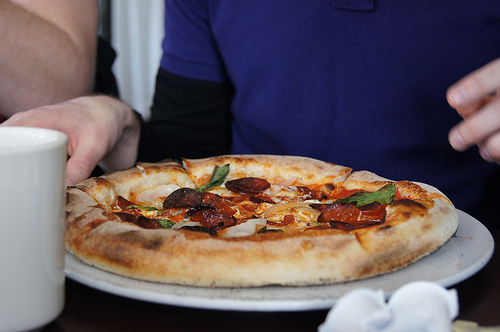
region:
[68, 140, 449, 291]
a pizza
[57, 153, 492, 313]
a pizza on a white plate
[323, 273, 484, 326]
a white crumpled napkin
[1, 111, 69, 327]
a white mug on a table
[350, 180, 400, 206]
a basil leaf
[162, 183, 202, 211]
a burned pepperoni slice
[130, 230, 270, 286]
a pizza crust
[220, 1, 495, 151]
a blue shirt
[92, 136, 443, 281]
a pizza with pepperoni and basil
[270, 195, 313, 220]
cheese on a pizza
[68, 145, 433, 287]
A round pizza on the plate.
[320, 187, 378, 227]
The pizza has pepperoni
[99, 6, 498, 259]
A person with a pizza in front of them.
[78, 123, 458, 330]
The pizza is on a white plate.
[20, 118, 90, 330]
A white cup is next to the plate.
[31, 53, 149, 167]
A person hand on the table.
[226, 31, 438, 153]
The person is wearing a blue shirt.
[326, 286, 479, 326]
A white napkin on the table.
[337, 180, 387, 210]
The pizza has spinach on top.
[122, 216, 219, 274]
The crust of the pizza is well done.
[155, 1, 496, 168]
Person wearing a blue shirt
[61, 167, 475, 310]
Pizza on a plate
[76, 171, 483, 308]
The plate is round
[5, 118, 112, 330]
The mug is white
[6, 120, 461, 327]
The mug is next to the plate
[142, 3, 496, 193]
Person wearing a long sleeve black shirt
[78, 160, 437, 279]
The pizza has a brown crust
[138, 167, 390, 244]
Red pepperoni on the pizza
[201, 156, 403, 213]
Green leaves on the pizza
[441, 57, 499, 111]
the finger of a person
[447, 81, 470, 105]
the finger nail of a person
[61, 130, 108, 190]
the thumb of a person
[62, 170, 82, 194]
the thumb nail of a person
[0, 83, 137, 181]
the hand of a person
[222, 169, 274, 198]
a piece of pepperoni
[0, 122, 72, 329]
a white coffee mug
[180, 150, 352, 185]
the crust of a pizza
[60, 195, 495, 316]
a white porcelain plate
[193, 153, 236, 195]
a green leaf on the pizza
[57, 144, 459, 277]
a pizza with toppings.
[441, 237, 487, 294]
a white plate.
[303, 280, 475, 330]
marina sauce to put on the pizza.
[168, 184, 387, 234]
a pepperoni topping.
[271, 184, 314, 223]
a cheese topping.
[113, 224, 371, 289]
a form of dough.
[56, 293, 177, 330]
a dark brown table.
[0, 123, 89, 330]
a white drinking cup.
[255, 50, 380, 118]
a man is wearing a blue shirt.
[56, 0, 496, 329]
a man is going to eat a pizza.